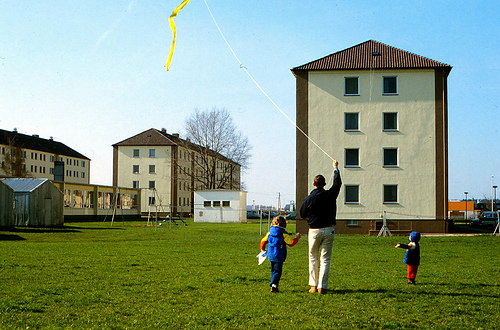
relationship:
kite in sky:
[159, 0, 193, 74] [34, 12, 161, 53]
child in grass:
[258, 215, 301, 292] [52, 239, 207, 294]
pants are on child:
[406, 263, 420, 283] [395, 227, 423, 284]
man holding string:
[291, 164, 346, 295] [208, 12, 289, 105]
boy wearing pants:
[366, 201, 454, 321] [399, 257, 429, 283]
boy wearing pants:
[395, 231, 421, 284] [264, 256, 285, 290]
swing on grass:
[103, 186, 168, 226] [4, 217, 498, 328]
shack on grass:
[187, 183, 249, 230] [135, 234, 232, 288]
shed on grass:
[7, 176, 66, 233] [4, 217, 498, 328]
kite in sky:
[164, 0, 192, 70] [47, 23, 164, 99]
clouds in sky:
[12, 69, 107, 138] [4, 3, 169, 113]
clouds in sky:
[42, 43, 206, 114] [3, 1, 490, 215]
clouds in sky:
[22, 47, 129, 149] [11, 5, 498, 178]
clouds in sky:
[23, 36, 256, 106] [3, 1, 490, 215]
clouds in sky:
[56, 26, 178, 172] [14, 17, 468, 189]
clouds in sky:
[33, 23, 248, 110] [3, 1, 490, 215]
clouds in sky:
[50, 16, 260, 109] [3, 1, 490, 215]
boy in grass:
[395, 231, 421, 284] [9, 229, 484, 320]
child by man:
[233, 182, 283, 296] [294, 175, 352, 309]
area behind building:
[4, 230, 498, 322] [112, 128, 244, 218]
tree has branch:
[181, 100, 253, 190] [205, 123, 212, 125]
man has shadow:
[298, 164, 345, 295] [323, 286, 497, 301]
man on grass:
[298, 164, 345, 295] [4, 217, 498, 328]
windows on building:
[379, 79, 393, 94] [108, 140, 239, 221]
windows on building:
[347, 76, 357, 97] [108, 140, 239, 221]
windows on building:
[381, 108, 402, 128] [108, 140, 239, 221]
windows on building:
[346, 112, 358, 131] [108, 140, 239, 221]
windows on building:
[383, 150, 395, 166] [108, 140, 239, 221]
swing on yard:
[103, 186, 168, 226] [4, 221, 314, 326]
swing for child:
[87, 179, 184, 236] [258, 215, 301, 292]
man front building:
[298, 164, 345, 295] [289, 36, 452, 234]